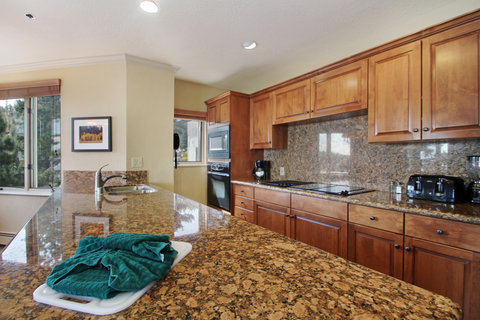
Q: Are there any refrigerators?
A: No, there are no refrigerators.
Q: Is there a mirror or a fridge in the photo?
A: No, there are no refrigerators or mirrors.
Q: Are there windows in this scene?
A: Yes, there is a window.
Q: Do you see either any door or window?
A: Yes, there is a window.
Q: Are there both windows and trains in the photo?
A: No, there is a window but no trains.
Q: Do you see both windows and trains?
A: No, there is a window but no trains.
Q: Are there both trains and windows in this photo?
A: No, there is a window but no trains.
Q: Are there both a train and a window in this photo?
A: No, there is a window but no trains.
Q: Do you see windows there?
A: Yes, there is a window.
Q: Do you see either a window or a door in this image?
A: Yes, there is a window.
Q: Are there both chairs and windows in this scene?
A: No, there is a window but no chairs.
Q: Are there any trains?
A: No, there are no trains.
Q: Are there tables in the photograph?
A: Yes, there is a table.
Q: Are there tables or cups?
A: Yes, there is a table.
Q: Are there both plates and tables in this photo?
A: No, there is a table but no plates.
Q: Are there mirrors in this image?
A: No, there are no mirrors.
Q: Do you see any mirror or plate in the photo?
A: No, there are no mirrors or plates.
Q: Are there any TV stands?
A: No, there are no TV stands.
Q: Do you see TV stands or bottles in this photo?
A: No, there are no TV stands or bottles.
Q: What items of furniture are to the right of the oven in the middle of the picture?
A: The pieces of furniture are drawers.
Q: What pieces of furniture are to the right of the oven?
A: The pieces of furniture are drawers.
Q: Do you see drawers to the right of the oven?
A: Yes, there are drawers to the right of the oven.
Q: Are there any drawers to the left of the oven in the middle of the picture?
A: No, the drawers are to the right of the oven.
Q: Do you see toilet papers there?
A: No, there are no toilet papers.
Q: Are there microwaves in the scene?
A: Yes, there is a microwave.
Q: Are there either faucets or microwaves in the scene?
A: Yes, there is a microwave.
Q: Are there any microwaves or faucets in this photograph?
A: Yes, there is a microwave.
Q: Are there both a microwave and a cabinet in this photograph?
A: Yes, there are both a microwave and a cabinet.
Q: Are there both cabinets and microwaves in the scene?
A: Yes, there are both a microwave and cabinets.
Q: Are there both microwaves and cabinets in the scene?
A: Yes, there are both a microwave and cabinets.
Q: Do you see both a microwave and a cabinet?
A: Yes, there are both a microwave and a cabinet.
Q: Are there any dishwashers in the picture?
A: No, there are no dishwashers.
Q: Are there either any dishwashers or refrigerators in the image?
A: No, there are no dishwashers or refrigerators.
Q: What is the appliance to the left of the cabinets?
A: The appliance is a microwave.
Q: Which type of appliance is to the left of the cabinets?
A: The appliance is a microwave.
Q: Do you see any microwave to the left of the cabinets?
A: Yes, there is a microwave to the left of the cabinets.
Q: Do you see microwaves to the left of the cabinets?
A: Yes, there is a microwave to the left of the cabinets.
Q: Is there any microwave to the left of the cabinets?
A: Yes, there is a microwave to the left of the cabinets.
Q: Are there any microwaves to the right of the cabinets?
A: No, the microwave is to the left of the cabinets.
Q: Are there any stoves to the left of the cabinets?
A: No, there is a microwave to the left of the cabinets.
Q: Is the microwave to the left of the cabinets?
A: Yes, the microwave is to the left of the cabinets.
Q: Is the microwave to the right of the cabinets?
A: No, the microwave is to the left of the cabinets.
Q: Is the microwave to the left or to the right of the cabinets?
A: The microwave is to the left of the cabinets.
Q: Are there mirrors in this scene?
A: No, there are no mirrors.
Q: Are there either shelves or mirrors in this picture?
A: No, there are no mirrors or shelves.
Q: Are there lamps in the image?
A: No, there are no lamps.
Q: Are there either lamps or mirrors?
A: No, there are no lamps or mirrors.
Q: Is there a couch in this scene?
A: No, there are no couches.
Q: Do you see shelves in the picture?
A: No, there are no shelves.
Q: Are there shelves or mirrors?
A: No, there are no shelves or mirrors.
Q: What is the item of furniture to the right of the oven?
A: The piece of furniture is a drawer.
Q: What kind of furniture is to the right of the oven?
A: The piece of furniture is a drawer.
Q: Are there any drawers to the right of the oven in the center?
A: Yes, there is a drawer to the right of the oven.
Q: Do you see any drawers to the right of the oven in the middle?
A: Yes, there is a drawer to the right of the oven.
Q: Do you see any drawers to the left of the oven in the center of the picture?
A: No, the drawer is to the right of the oven.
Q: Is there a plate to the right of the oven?
A: No, there is a drawer to the right of the oven.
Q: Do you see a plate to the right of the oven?
A: No, there is a drawer to the right of the oven.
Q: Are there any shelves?
A: No, there are no shelves.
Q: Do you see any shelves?
A: No, there are no shelves.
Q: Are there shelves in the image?
A: No, there are no shelves.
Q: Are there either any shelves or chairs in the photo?
A: No, there are no shelves or chairs.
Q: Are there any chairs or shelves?
A: No, there are no shelves or chairs.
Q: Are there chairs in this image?
A: No, there are no chairs.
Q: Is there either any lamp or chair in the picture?
A: No, there are no chairs or lamps.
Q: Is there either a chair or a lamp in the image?
A: No, there are no chairs or lamps.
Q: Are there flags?
A: No, there are no flags.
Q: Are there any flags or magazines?
A: No, there are no flags or magazines.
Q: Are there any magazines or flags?
A: No, there are no flags or magazines.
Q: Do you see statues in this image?
A: No, there are no statues.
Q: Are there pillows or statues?
A: No, there are no statues or pillows.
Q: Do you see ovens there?
A: Yes, there is an oven.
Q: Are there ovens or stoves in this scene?
A: Yes, there is an oven.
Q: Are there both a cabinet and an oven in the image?
A: Yes, there are both an oven and a cabinet.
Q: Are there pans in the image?
A: No, there are no pans.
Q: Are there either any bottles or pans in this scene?
A: No, there are no pans or bottles.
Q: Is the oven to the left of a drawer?
A: Yes, the oven is to the left of a drawer.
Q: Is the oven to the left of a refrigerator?
A: No, the oven is to the left of a drawer.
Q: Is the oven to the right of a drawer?
A: No, the oven is to the left of a drawer.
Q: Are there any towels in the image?
A: Yes, there is a towel.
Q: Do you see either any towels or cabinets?
A: Yes, there is a towel.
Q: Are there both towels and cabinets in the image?
A: Yes, there are both a towel and a cabinet.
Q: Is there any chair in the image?
A: No, there are no chairs.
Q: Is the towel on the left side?
A: Yes, the towel is on the left of the image.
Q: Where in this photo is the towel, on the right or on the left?
A: The towel is on the left of the image.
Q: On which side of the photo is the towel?
A: The towel is on the left of the image.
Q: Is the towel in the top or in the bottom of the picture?
A: The towel is in the bottom of the image.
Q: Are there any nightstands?
A: No, there are no nightstands.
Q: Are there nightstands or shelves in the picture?
A: No, there are no nightstands or shelves.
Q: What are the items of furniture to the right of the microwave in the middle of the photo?
A: The pieces of furniture are cabinets.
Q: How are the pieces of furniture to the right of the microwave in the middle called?
A: The pieces of furniture are cabinets.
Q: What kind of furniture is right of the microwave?
A: The pieces of furniture are cabinets.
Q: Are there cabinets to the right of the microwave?
A: Yes, there are cabinets to the right of the microwave.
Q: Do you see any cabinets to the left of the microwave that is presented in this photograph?
A: No, the cabinets are to the right of the microwave.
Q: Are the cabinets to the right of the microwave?
A: Yes, the cabinets are to the right of the microwave.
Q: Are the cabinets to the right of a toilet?
A: No, the cabinets are to the right of the microwave.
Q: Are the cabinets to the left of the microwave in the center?
A: No, the cabinets are to the right of the microwave.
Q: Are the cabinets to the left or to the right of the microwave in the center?
A: The cabinets are to the right of the microwave.